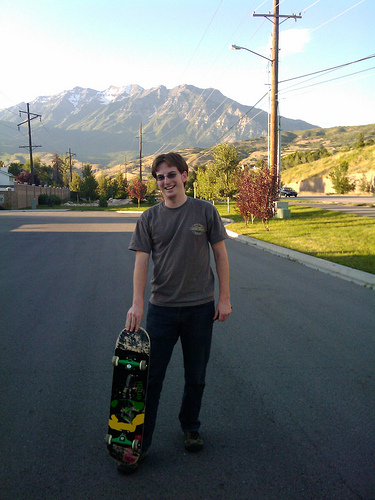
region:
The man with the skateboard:
[101, 150, 232, 470]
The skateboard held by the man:
[102, 325, 152, 472]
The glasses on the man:
[155, 170, 182, 182]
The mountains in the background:
[1, 81, 322, 145]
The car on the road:
[273, 182, 298, 199]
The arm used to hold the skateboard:
[120, 226, 152, 334]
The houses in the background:
[0, 164, 17, 192]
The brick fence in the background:
[1, 181, 70, 212]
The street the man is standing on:
[1, 208, 372, 499]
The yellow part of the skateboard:
[107, 413, 146, 431]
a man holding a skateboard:
[102, 140, 253, 442]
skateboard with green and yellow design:
[110, 322, 163, 477]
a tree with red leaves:
[231, 160, 295, 239]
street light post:
[225, 3, 311, 226]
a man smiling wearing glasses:
[117, 150, 252, 456]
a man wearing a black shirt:
[106, 154, 242, 452]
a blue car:
[278, 182, 302, 201]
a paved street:
[12, 204, 118, 340]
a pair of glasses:
[154, 170, 183, 182]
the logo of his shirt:
[189, 218, 211, 245]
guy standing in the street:
[71, 154, 238, 482]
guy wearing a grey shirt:
[125, 153, 227, 472]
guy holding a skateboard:
[78, 136, 244, 478]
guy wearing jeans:
[96, 156, 243, 484]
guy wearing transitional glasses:
[89, 133, 261, 472]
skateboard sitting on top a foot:
[109, 315, 163, 498]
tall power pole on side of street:
[255, 5, 309, 220]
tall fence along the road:
[11, 178, 75, 209]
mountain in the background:
[17, 77, 244, 165]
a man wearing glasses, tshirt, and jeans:
[107, 148, 246, 462]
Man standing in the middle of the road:
[98, 150, 233, 476]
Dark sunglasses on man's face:
[150, 167, 174, 178]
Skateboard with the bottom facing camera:
[105, 320, 150, 465]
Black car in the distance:
[278, 183, 294, 194]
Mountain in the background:
[11, 70, 305, 190]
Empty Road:
[15, 217, 342, 483]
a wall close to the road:
[0, 174, 71, 205]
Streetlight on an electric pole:
[225, 36, 270, 60]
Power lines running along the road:
[143, 0, 368, 151]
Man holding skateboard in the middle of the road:
[101, 150, 217, 465]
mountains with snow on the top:
[11, 79, 305, 160]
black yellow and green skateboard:
[98, 319, 170, 494]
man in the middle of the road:
[114, 154, 234, 485]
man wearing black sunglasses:
[137, 154, 202, 216]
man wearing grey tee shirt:
[127, 157, 232, 449]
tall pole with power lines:
[254, 7, 372, 247]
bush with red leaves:
[231, 170, 286, 230]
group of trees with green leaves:
[20, 157, 138, 208]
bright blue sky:
[35, 13, 355, 98]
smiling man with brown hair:
[125, 149, 241, 342]